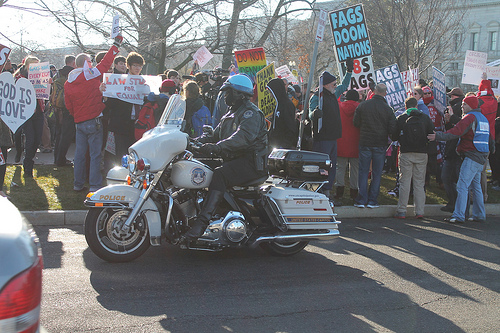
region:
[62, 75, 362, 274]
a motorcycle on the street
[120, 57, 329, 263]
a police officer on the bike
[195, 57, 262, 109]
police is wearing a helmet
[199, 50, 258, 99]
the helmet is blue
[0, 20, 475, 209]
people are gathered together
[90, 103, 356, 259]
the bike is white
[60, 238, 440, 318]
shadow of the bike on the ground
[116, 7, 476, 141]
people are carrying signs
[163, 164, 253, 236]
the cop os wearing boots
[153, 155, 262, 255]
the boots are black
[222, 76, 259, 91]
The helmet the cop is wearing.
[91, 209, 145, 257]
The front tire of the motorcycle.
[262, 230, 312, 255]
The back tire of the motorcycle.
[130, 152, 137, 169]
The front headlight of the motorcycle.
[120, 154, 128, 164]
The blue light on the front of the motorcycle.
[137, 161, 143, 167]
The red light on the front of the motorcycle.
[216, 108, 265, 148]
The jacket the cop is wearing.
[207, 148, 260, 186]
The pants the cop is wearing.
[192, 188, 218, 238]
The boot the cop is wearing.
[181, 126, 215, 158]
The handle bars of the motorcycle.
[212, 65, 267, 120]
Person wearing helmet on head.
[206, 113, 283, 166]
Person wearing black coat.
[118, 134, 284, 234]
Person sitting on white motorcycle.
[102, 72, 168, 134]
Person holding white sign with red writing.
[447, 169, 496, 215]
Person wearing blue pants.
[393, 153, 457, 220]
Person wearing khaki pants.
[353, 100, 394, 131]
Person wearing black jacket.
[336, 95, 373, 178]
Person wearing red coat.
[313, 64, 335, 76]
Hat on person's head.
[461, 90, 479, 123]
Red hat on man's head.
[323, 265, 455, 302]
shadow cast on the street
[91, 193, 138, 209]
wording on side of bike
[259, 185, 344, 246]
white container on side of bike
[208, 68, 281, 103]
blue and black helmet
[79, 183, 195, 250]
white cover over wheel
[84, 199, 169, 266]
black wheel on bike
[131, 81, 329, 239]
police officer on bike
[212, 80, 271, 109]
black mask on face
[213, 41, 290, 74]
rainbow color sign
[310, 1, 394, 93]
large blue and black sign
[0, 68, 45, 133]
Heart shaped sign says god is love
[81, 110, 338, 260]
This is a police motorcycle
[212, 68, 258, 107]
This policeman is wearing a helmet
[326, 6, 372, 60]
This sign says fags doom nations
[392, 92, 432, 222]
This man is sstanding on the street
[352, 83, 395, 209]
This man is standing on the street curb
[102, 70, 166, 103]
This sign says law students for equality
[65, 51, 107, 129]
this man's jacket is red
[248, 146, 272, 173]
The police officer has a gun in his holster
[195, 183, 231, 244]
The police officer is wearing boots